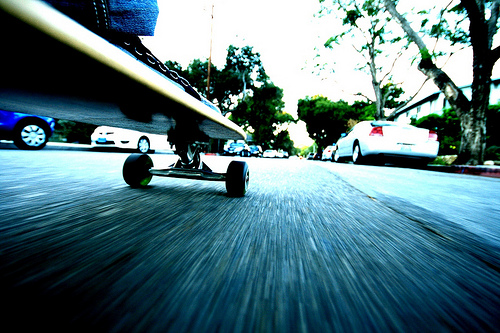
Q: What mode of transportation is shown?
A: Cars.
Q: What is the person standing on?
A: Skateboard.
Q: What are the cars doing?
A: Parked.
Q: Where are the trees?
A: Beside the road.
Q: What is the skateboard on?
A: Road.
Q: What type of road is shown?
A: Paved.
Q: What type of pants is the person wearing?
A: Jeans.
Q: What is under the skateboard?
A: Wheels.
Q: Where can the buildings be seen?
A: Right side of the image.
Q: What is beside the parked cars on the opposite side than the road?
A: Sidewalk.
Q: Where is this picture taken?
A: Street.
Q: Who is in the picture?
A: A skateboarder.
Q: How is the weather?
A: Sunny.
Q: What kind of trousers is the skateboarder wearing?
A: Jeans.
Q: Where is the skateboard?
A: The foreground.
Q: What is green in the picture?
A: Trees.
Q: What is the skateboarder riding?
A: Skateboard.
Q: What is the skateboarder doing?
A: Skateboarding.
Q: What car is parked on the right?
A: White car.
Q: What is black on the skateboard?
A: Wheels.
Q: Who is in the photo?
A: A skater.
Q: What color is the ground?
A: Black.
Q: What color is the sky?
A: White.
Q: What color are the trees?
A: Green.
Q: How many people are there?
A: One.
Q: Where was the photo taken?
A: On the road.